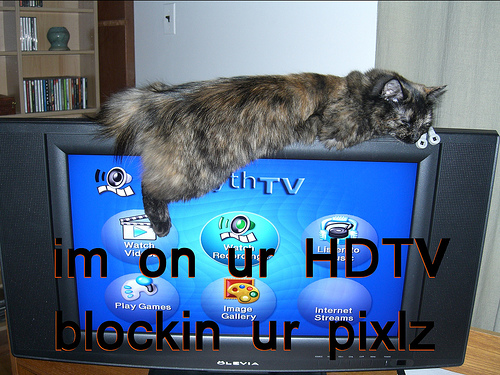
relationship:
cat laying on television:
[82, 68, 447, 236] [2, 117, 498, 374]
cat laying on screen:
[111, 61, 436, 206] [67, 153, 419, 339]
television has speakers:
[2, 117, 498, 366] [1, 120, 498, 366]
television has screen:
[2, 117, 498, 366] [61, 142, 419, 342]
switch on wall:
[160, 2, 174, 27] [151, 1, 184, 44]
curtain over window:
[367, 0, 497, 149] [369, 6, 498, 338]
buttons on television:
[304, 350, 416, 360] [2, 117, 498, 366]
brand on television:
[216, 357, 263, 368] [2, 117, 498, 366]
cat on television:
[82, 68, 447, 236] [2, 117, 498, 374]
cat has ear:
[82, 68, 447, 236] [378, 69, 405, 99]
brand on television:
[216, 359, 259, 366] [2, 117, 498, 366]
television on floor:
[2, 117, 498, 366] [17, 335, 497, 372]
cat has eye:
[82, 68, 447, 236] [397, 116, 413, 130]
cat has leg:
[82, 68, 447, 236] [129, 145, 186, 245]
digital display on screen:
[65, 146, 422, 342] [5, 111, 497, 363]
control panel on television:
[314, 354, 411, 369] [2, 117, 498, 366]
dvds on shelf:
[43, 79, 48, 112] [24, 55, 104, 115]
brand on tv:
[216, 359, 259, 366] [13, 105, 476, 353]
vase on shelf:
[47, 26, 72, 50] [19, 7, 99, 55]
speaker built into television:
[418, 114, 492, 368] [3, 70, 496, 366]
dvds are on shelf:
[23, 77, 87, 112] [15, 105, 100, 123]